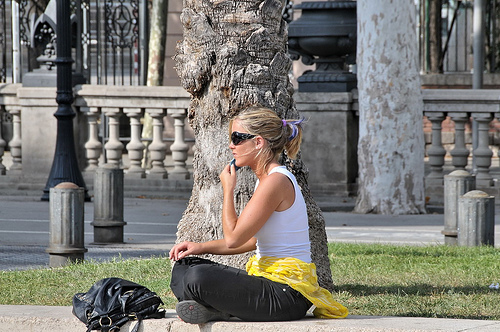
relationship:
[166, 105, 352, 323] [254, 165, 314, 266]
woman wearing shirt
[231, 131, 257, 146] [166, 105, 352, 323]
sunglasses on woman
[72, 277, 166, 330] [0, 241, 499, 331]
handbag on ground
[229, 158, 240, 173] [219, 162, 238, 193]
phone in hand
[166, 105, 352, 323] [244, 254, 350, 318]
woman has clothing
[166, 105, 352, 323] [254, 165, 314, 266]
woman in tank top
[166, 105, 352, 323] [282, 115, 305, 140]
woman with hair tie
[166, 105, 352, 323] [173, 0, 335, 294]
woman by tree trunk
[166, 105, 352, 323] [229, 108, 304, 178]
woman with hair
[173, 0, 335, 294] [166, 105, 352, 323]
tree trunk beside woman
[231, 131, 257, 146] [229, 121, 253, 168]
sunglasses on woman's face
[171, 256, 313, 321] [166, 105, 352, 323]
pants on woman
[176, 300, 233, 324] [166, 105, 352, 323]
shoe on woman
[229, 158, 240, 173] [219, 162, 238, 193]
cell phone in hand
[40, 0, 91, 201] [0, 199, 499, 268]
lamp post by road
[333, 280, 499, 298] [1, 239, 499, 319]
shadow in grass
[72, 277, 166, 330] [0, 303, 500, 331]
handbag on curb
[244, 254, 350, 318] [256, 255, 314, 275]
clothing on woman's waist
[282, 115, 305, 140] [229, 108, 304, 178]
ribbon in woman's hair